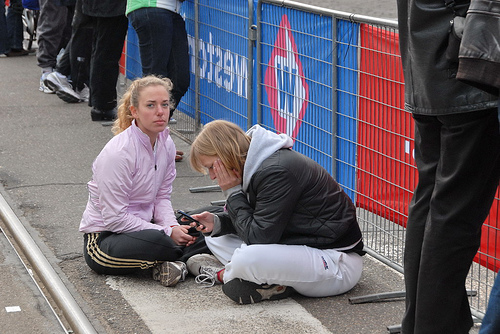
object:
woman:
[81, 74, 366, 306]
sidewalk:
[1, 47, 498, 333]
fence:
[119, 0, 499, 332]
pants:
[203, 234, 364, 296]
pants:
[83, 206, 226, 275]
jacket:
[203, 123, 361, 252]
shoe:
[186, 253, 225, 285]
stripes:
[84, 230, 162, 269]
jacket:
[397, 0, 499, 115]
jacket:
[78, 119, 180, 237]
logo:
[263, 14, 309, 150]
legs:
[2, 0, 190, 130]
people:
[1, 1, 198, 126]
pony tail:
[109, 79, 134, 137]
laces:
[195, 269, 216, 287]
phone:
[178, 210, 206, 229]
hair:
[111, 74, 175, 136]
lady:
[78, 74, 213, 288]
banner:
[128, 2, 500, 272]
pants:
[81, 0, 128, 114]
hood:
[242, 124, 293, 193]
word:
[186, 31, 257, 100]